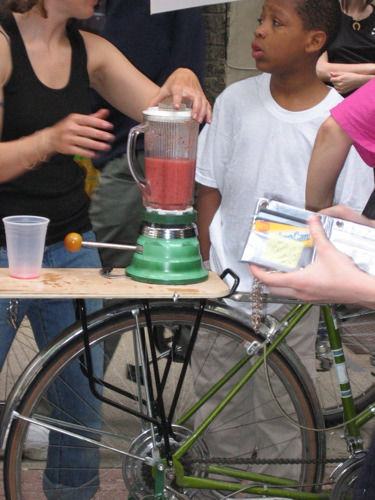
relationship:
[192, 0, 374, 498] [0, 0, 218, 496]
boy learning from teacher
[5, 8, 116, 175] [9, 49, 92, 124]
woman wearing tank top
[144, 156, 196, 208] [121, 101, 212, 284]
liquid in blender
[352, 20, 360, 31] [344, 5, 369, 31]
horseshoe charm on necklace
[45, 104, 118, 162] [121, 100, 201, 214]
hand making drink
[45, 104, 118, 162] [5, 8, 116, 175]
hand of woman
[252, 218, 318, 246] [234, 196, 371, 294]
card in wallet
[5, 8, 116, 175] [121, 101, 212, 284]
woman holding blender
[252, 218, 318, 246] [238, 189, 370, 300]
card with wallet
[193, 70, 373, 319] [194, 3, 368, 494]
t-shirt of child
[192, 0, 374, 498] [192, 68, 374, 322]
boy wearing shirt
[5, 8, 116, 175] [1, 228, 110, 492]
woman wearing blue jeans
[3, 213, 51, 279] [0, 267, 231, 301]
cup on platform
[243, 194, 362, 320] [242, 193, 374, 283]
person holding wallet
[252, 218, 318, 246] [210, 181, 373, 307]
card in wallet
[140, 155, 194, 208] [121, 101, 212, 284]
smoothie in blender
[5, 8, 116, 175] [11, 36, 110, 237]
woman wearing shirt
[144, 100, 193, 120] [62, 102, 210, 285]
lid on blender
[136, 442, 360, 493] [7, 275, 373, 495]
chain on bike